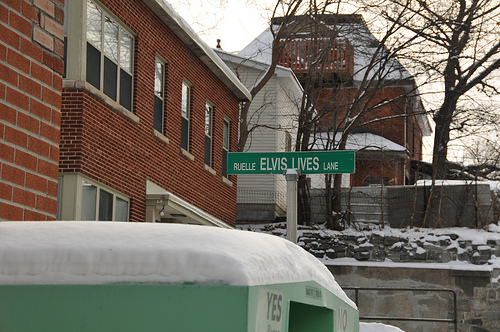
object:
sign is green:
[223, 150, 370, 186]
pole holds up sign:
[282, 169, 303, 242]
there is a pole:
[283, 171, 300, 239]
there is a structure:
[0, 222, 360, 332]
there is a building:
[1, 1, 251, 231]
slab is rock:
[330, 258, 498, 331]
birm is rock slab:
[307, 222, 499, 332]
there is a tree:
[239, 1, 420, 228]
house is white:
[210, 8, 434, 222]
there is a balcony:
[269, 27, 361, 83]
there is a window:
[82, 2, 138, 115]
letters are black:
[262, 288, 286, 325]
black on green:
[1, 281, 359, 332]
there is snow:
[1, 220, 309, 285]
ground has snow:
[235, 218, 498, 269]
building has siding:
[58, 1, 95, 80]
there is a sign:
[255, 287, 294, 331]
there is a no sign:
[334, 303, 359, 332]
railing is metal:
[343, 279, 461, 331]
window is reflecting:
[84, 1, 138, 73]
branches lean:
[284, 1, 345, 120]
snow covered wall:
[232, 215, 494, 273]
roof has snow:
[239, 10, 407, 75]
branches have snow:
[331, 82, 431, 154]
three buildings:
[1, 0, 246, 220]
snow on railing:
[299, 187, 391, 230]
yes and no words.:
[265, 293, 347, 332]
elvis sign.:
[227, 152, 355, 175]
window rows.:
[87, 3, 239, 188]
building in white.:
[226, 57, 305, 210]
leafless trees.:
[283, 0, 490, 233]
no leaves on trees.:
[359, 0, 499, 178]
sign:
[216, 145, 349, 173]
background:
[243, 0, 497, 117]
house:
[224, 10, 430, 187]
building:
[224, 6, 423, 187]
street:
[188, 151, 417, 329]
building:
[0, 0, 259, 230]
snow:
[1, 206, 361, 309]